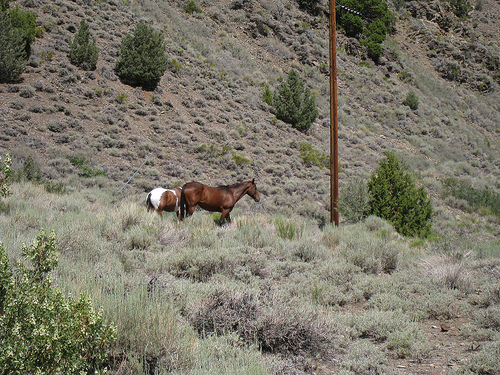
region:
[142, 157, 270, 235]
brown horse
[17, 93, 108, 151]
short green and yellow grass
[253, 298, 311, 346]
short green and yellow grass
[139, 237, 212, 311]
short green and yellow grass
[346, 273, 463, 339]
short green and yellow grass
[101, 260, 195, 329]
short green and yellow grass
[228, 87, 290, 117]
short green and yellow grass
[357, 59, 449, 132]
short green and yellow grass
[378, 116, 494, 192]
short green and yellow grass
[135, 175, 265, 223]
two horses on a hill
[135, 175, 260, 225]
two horses standing on hill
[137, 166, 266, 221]
two horses standing together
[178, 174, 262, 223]
large brown horse on hill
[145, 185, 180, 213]
brown and white horse on hill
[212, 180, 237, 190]
black mane on a horse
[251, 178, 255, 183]
black ear on top of horse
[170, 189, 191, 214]
long black tail of horse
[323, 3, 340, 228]
tall brown post on ihll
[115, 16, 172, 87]
green bush growing on side of hill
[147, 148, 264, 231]
two horses on a field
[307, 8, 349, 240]
a pole on a field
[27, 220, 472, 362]
bushes and grasses on a field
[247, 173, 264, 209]
head of a horse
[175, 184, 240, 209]
body of a horse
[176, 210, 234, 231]
legs of a horse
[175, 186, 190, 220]
tail of a horse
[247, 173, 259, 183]
ear of a horse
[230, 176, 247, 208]
neck of a horse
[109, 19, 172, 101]
a bush on a field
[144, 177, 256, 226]
two horses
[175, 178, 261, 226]
brown horse with black mane and tail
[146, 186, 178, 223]
white and brown horse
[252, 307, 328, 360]
silver-gray sagebrush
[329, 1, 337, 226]
round wood utility pole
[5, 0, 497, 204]
rocky hillside with sagebrush and small trees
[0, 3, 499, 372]
two horses descending from hills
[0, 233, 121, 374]
high desert vegetation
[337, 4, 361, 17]
electrical wire insulator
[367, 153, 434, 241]
tree growing on hillside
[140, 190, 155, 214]
tail of a horse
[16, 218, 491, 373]
a grassy field with bushes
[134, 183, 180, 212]
body of a horse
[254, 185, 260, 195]
eye of a horse